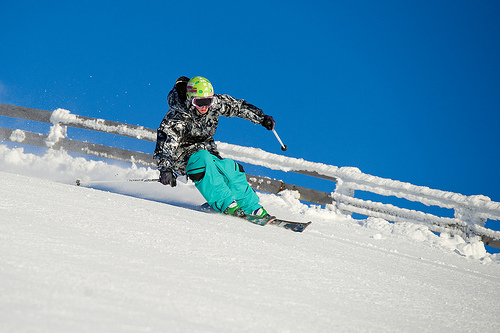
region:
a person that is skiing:
[72, 32, 388, 332]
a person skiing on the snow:
[80, 43, 413, 325]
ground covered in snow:
[241, 275, 322, 307]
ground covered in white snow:
[284, 241, 431, 328]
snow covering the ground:
[161, 253, 363, 328]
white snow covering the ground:
[76, 196, 351, 326]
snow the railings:
[310, 121, 492, 261]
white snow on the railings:
[302, 111, 491, 286]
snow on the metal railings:
[279, 127, 487, 274]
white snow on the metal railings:
[280, 126, 455, 281]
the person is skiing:
[100, 51, 333, 261]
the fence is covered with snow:
[275, 132, 480, 274]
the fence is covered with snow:
[294, 136, 414, 246]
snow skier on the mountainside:
[150, 70, 313, 232]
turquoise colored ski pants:
[186, 149, 262, 217]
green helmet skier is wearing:
[186, 76, 214, 103]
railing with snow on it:
[1, 102, 498, 255]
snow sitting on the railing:
[1, 101, 498, 252]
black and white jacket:
[153, 95, 263, 172]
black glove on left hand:
[258, 112, 278, 131]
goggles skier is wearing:
[188, 97, 216, 106]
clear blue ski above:
[1, 0, 498, 252]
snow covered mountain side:
[0, 142, 499, 332]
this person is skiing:
[73, 34, 380, 264]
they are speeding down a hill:
[77, 38, 364, 255]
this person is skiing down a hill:
[65, 33, 354, 254]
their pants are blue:
[164, 133, 286, 240]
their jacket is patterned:
[112, 42, 292, 194]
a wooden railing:
[1, 80, 498, 265]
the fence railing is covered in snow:
[2, 90, 496, 251]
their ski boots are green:
[195, 174, 288, 229]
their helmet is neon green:
[147, 63, 247, 130]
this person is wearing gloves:
[87, 33, 378, 275]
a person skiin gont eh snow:
[83, 33, 315, 306]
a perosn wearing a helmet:
[122, 61, 364, 268]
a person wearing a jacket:
[140, 46, 261, 171]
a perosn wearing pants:
[135, 26, 330, 305]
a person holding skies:
[160, 51, 280, 198]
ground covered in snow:
[94, 233, 212, 323]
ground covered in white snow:
[68, 272, 165, 323]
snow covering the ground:
[66, 253, 158, 323]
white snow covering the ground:
[39, 226, 131, 301]